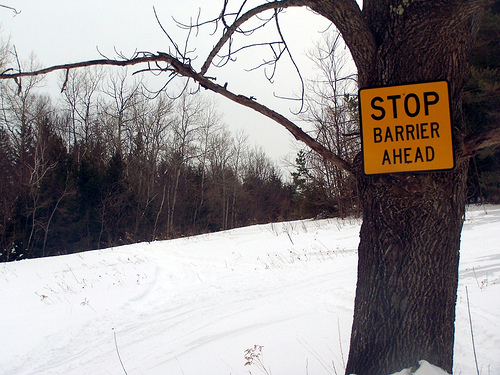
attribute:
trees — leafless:
[2, 90, 294, 262]